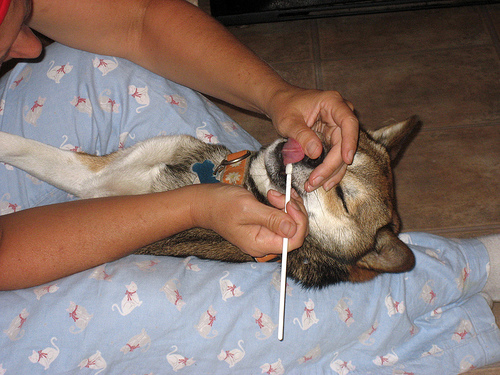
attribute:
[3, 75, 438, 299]
dog — bottom half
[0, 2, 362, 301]
woman — laying down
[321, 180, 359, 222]
eye — closed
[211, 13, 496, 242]
floor — brown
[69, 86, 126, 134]
print — white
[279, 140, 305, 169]
tounge — out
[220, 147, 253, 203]
collar — orange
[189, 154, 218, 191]
tag — blue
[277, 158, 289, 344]
toothbrush — white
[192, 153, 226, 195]
id tag — bone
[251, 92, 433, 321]
head — dog's